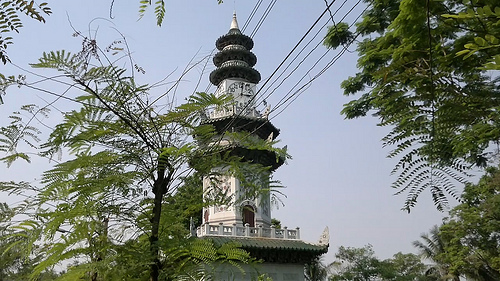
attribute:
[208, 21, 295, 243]
temple — white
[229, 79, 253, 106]
clock — white, tower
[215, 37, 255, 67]
tower — white, top, ponit, here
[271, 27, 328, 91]
lines — grey, set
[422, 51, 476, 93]
trees — green, here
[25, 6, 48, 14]
leaves — here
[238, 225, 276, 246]
railing — white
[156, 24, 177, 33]
sky — blue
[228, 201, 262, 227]
door — brown, here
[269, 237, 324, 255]
roof — green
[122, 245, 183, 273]
trunk — narrow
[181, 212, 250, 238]
balcony — here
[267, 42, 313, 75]
wires — here